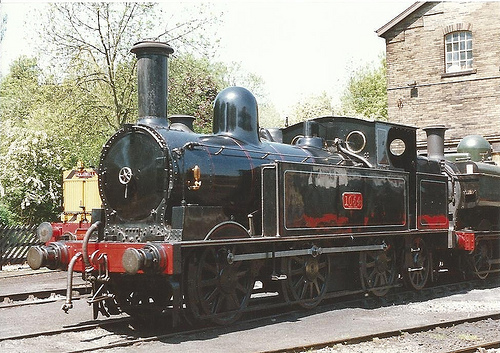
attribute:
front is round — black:
[96, 121, 179, 222]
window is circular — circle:
[345, 130, 366, 156]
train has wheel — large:
[358, 230, 399, 306]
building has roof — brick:
[366, 1, 438, 39]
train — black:
[25, 36, 498, 334]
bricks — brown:
[428, 165, 459, 195]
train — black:
[65, 136, 490, 225]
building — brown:
[374, 52, 484, 118]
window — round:
[437, 50, 474, 120]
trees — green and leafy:
[7, 68, 94, 217]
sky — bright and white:
[241, 67, 299, 124]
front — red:
[24, 257, 194, 353]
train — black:
[96, 111, 497, 310]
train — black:
[77, 88, 488, 326]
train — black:
[199, 114, 472, 224]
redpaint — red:
[74, 258, 179, 353]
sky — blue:
[186, 51, 272, 59]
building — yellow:
[39, 120, 121, 219]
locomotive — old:
[56, 13, 449, 315]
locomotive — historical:
[79, 87, 466, 324]